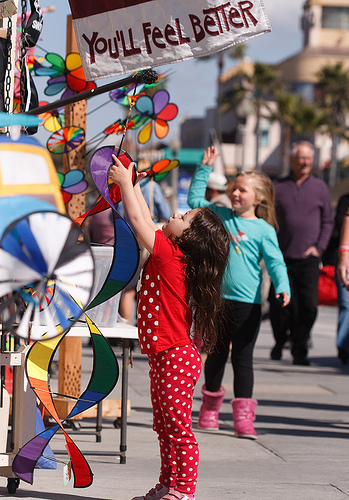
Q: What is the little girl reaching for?
A: Colorful wind spinners.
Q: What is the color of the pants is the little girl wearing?
A: Red with white polka dots.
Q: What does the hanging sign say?
A: You'll feel better.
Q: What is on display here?
A: Colorful wind spinners.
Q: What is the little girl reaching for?
A: Colorful wind spinner.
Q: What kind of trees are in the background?
A: Palm trees.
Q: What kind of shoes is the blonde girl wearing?
A: Boots.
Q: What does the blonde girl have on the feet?
A: Pink boots.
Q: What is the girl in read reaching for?
A: A pinwheel.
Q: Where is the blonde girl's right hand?
A: In the air.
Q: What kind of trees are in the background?
A: Palm.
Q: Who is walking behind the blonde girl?
A: A man in a purple shirt.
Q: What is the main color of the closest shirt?
A: Red.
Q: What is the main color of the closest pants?
A: Red.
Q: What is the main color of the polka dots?
A: White.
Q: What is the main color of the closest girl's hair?
A: Brown.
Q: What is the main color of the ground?
A: Gray.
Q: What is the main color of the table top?
A: White.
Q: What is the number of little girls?
A: 2.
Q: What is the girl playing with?
A: A pinwheel.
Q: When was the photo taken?
A: In daytime.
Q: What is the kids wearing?
A: Clothes.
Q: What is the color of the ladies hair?
A: Brown.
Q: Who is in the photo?
A: People.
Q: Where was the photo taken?
A: On the sidewalk.